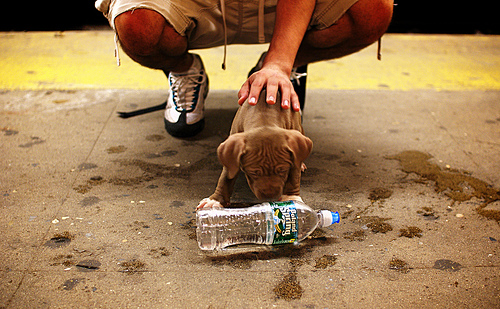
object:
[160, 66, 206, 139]
shoe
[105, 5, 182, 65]
knee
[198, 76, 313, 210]
dog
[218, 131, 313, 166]
ears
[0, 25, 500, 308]
sidewalk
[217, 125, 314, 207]
head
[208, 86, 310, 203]
puppy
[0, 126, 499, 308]
water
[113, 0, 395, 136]
person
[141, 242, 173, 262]
print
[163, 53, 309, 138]
shoes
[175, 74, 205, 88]
slaces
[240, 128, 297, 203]
face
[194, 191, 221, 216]
paw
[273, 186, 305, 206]
paw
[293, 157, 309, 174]
paw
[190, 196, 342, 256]
bottle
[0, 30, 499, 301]
ground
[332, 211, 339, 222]
cap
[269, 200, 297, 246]
label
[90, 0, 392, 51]
shorts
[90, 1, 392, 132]
man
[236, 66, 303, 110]
hand